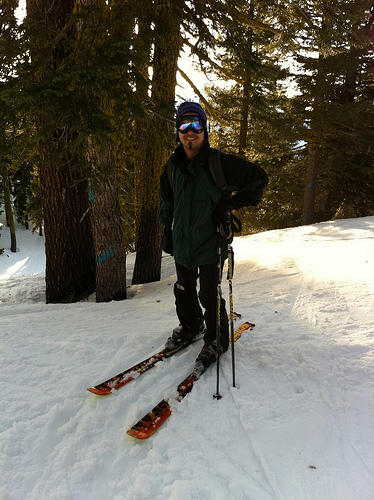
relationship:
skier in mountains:
[162, 98, 269, 381] [4, 199, 374, 494]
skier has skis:
[162, 98, 269, 381] [89, 303, 257, 442]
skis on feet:
[89, 303, 257, 442] [161, 324, 230, 370]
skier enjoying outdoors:
[162, 98, 269, 381] [4, 8, 370, 494]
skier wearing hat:
[162, 98, 269, 381] [176, 101, 210, 128]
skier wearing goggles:
[162, 98, 269, 381] [178, 115, 205, 133]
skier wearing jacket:
[162, 98, 269, 381] [158, 145, 263, 268]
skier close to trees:
[162, 98, 269, 381] [4, 8, 370, 494]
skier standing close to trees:
[162, 98, 269, 381] [1, 4, 374, 306]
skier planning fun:
[162, 98, 269, 381] [10, 0, 370, 490]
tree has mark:
[91, 134, 129, 299] [89, 183, 125, 275]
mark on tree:
[89, 183, 125, 275] [91, 134, 129, 299]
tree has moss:
[133, 0, 195, 290] [146, 5, 186, 216]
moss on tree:
[146, 5, 186, 216] [133, 0, 195, 290]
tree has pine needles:
[281, 16, 366, 218] [289, 1, 373, 178]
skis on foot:
[124, 320, 256, 442] [193, 341, 229, 371]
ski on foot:
[78, 310, 242, 402] [165, 322, 203, 353]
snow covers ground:
[2, 213, 374, 491] [2, 216, 373, 493]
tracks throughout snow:
[4, 199, 374, 494] [2, 213, 374, 491]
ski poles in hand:
[215, 220, 239, 402] [209, 201, 235, 228]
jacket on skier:
[158, 145, 263, 268] [162, 98, 269, 381]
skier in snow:
[162, 98, 269, 381] [2, 213, 374, 491]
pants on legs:
[171, 262, 237, 341] [175, 258, 228, 336]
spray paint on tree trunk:
[85, 181, 122, 257] [88, 100, 125, 302]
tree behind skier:
[1, 1, 150, 314] [87, 96, 273, 439]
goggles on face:
[178, 115, 205, 133] [174, 115, 207, 156]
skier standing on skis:
[162, 98, 269, 381] [89, 303, 257, 442]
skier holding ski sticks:
[162, 98, 269, 381] [215, 230, 238, 399]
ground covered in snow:
[2, 216, 373, 493] [2, 213, 374, 491]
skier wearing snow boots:
[162, 98, 269, 381] [167, 319, 229, 369]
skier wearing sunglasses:
[162, 98, 269, 381] [178, 113, 205, 134]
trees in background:
[1, 4, 374, 306] [2, 4, 369, 328]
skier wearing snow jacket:
[162, 98, 269, 381] [161, 140, 266, 275]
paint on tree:
[91, 183, 122, 263] [91, 134, 129, 299]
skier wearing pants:
[162, 98, 269, 381] [171, 262, 237, 341]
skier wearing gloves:
[162, 98, 269, 381] [154, 197, 238, 255]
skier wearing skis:
[162, 98, 269, 381] [89, 303, 257, 442]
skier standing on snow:
[162, 98, 269, 381] [2, 213, 374, 491]